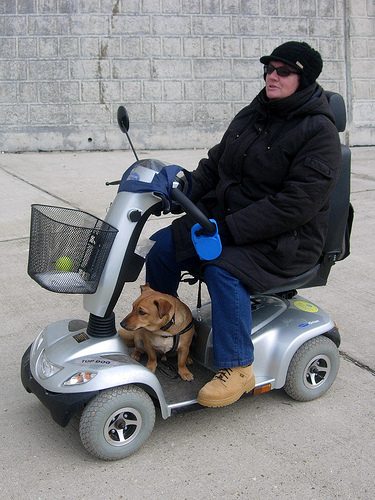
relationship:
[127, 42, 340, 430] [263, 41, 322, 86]
lady wearing hat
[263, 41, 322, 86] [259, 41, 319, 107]
hat on top of head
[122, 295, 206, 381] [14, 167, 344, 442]
dog sitting on scooter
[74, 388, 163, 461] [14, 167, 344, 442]
front tire of scooter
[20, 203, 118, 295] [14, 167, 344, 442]
basket on front of scooter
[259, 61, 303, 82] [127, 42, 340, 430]
sunglasses worn by lady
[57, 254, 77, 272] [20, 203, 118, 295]
ball in basket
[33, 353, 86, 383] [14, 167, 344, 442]
headlight of scooter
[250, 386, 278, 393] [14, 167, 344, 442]
reflector of scooter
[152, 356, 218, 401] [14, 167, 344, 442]
floor of scooter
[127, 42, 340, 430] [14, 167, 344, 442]
lady riding scooter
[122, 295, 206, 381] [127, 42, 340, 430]
dog below lady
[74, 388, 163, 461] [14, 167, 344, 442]
wheel of scooter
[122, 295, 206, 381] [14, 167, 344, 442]
dog riding scooter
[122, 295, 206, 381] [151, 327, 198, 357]
dog wearing harness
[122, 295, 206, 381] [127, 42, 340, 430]
dog sitting near lady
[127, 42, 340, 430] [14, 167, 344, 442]
lady sitting on scooter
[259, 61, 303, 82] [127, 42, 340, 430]
sunglasses on face of lady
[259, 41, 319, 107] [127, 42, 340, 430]
head of lady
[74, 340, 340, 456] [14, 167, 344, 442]
wheels on bottom of scooter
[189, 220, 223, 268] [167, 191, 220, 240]
leash hanging from handlebar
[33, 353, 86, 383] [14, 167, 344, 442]
headlight in front of scooter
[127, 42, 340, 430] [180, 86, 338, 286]
lady wearing jacket